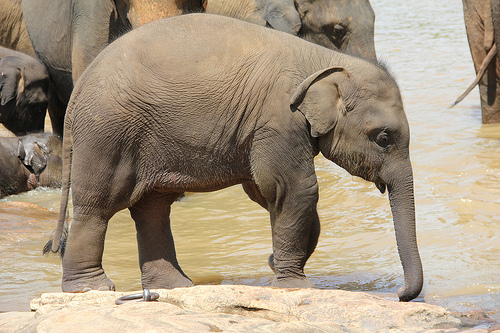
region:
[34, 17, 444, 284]
elephant are seen.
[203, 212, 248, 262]
water is brown color.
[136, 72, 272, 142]
elephants are grey color.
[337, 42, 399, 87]
elephants have short hair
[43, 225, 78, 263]
tail has black hair.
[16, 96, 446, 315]
elephants are playing in water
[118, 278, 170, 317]
round ring is seen in water.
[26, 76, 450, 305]
day time picture.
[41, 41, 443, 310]
day is bright sunny.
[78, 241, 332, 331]
shadow is seen in water.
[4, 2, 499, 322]
the photo is clear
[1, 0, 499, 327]
the photo was taken outside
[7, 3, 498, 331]
the photo was taken during the day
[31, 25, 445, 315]
animal are in the photo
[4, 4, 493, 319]
the animals are elephants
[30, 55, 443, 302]
the animal is standing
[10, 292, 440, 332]
a rock is in the photo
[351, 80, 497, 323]
the animal is looking down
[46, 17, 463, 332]
the elephant is standing on the rock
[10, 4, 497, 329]
the weather is calm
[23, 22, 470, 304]
baby elephant wading river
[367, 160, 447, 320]
elephant trunk slurping water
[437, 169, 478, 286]
brown water with ripples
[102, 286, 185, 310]
elephant excrement on a rock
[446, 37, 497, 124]
an elephant has a tail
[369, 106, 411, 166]
an eye looking at the camera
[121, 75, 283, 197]
an elephant with wrinkled skin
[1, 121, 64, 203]
an elephant swimming in the river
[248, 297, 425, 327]
a rock sitting in water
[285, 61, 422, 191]
a elephant head with a large ear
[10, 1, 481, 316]
animals are in the photo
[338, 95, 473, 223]
the elephant is looking down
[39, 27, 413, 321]
the elephant is standing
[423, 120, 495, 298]
waster is in the photo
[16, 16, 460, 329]
the elephant is standing on a rock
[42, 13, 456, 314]
baby elephant at edge of water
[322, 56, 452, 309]
truck on top of water surface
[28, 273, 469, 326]
large flat rock in front of elephant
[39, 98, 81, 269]
tail down with some hair at end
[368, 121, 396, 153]
large round deep-set eye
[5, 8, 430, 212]
other elephants standing and in the water behind baby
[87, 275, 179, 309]
metal ring on top of rock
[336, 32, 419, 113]
fuzzy dark hairs on top of head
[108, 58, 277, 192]
wrinkles and sags on body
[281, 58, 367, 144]
top of ear curled over